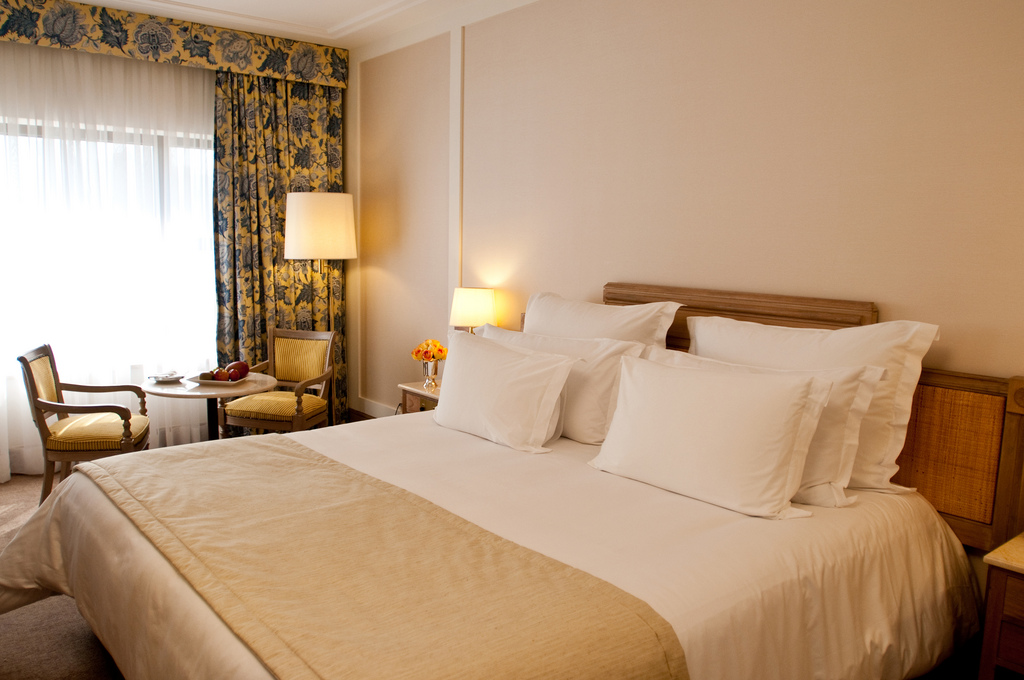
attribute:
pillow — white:
[427, 323, 580, 461]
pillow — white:
[466, 308, 650, 452]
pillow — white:
[517, 282, 683, 371]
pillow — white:
[582, 343, 830, 528]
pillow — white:
[671, 300, 944, 496]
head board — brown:
[586, 260, 1014, 559]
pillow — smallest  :
[589, 348, 812, 520]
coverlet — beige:
[172, 442, 572, 673]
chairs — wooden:
[232, 332, 324, 428]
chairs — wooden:
[25, 343, 137, 457]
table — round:
[133, 373, 271, 437]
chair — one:
[12, 326, 159, 508]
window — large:
[1, 1, 352, 485]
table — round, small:
[155, 359, 286, 424]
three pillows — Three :
[590, 314, 938, 515]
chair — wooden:
[16, 345, 153, 510]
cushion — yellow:
[47, 405, 150, 448]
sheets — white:
[6, 403, 977, 676]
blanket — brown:
[71, 431, 687, 676]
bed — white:
[57, 288, 1010, 662]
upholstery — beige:
[27, 362, 149, 436]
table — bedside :
[396, 376, 436, 407]